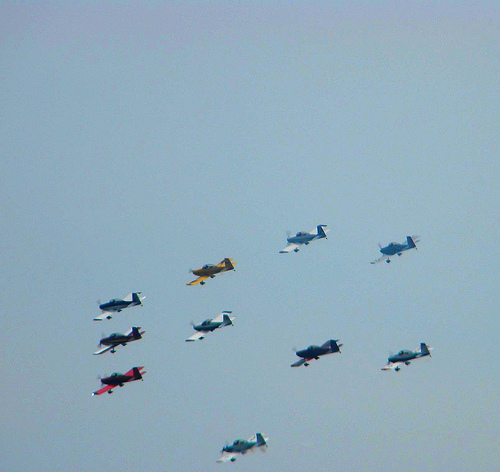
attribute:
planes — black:
[69, 159, 464, 439]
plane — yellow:
[182, 243, 254, 290]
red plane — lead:
[90, 365, 146, 397]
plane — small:
[277, 217, 332, 261]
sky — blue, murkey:
[2, 1, 499, 467]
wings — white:
[363, 254, 391, 270]